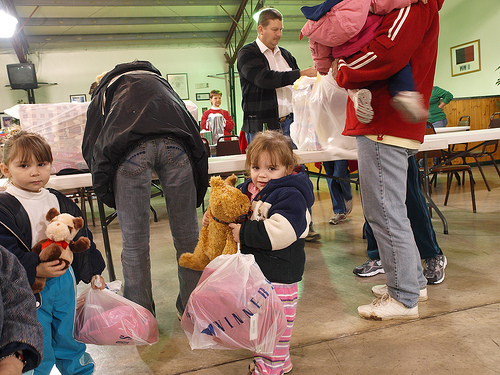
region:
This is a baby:
[2, 127, 109, 373]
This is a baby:
[191, 120, 331, 373]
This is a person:
[80, 50, 212, 354]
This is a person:
[231, 0, 321, 138]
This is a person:
[336, 7, 464, 357]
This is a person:
[197, 81, 238, 147]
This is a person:
[241, 5, 290, 141]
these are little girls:
[28, 69, 381, 341]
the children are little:
[33, 135, 316, 336]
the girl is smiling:
[210, 136, 332, 301]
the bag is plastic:
[209, 243, 296, 347]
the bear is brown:
[183, 177, 266, 264]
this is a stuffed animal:
[192, 169, 279, 284]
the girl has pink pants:
[269, 279, 331, 371]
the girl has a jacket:
[237, 178, 320, 285]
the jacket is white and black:
[241, 181, 350, 318]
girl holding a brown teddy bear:
[193, 181, 252, 258]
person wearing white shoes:
[350, 285, 421, 323]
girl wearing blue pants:
[31, 270, 85, 372]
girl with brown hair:
[3, 130, 51, 172]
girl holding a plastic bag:
[78, 265, 157, 354]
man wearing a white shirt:
[255, 40, 301, 114]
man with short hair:
[250, 0, 285, 35]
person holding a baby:
[306, 0, 451, 115]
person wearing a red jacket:
[362, 0, 441, 140]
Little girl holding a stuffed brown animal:
[177, 130, 315, 373]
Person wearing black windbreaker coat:
[82, 59, 208, 321]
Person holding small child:
[299, 0, 445, 320]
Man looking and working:
[237, 7, 316, 141]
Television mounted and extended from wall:
[5, 61, 57, 107]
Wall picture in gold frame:
[448, 38, 482, 78]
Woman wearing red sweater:
[200, 88, 235, 152]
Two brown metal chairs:
[448, 110, 499, 190]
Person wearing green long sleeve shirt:
[427, 84, 452, 127]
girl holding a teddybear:
[189, 132, 311, 347]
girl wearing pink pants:
[261, 276, 316, 373]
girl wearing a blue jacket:
[230, 181, 317, 289]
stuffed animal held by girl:
[26, 209, 92, 287]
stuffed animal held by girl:
[183, 170, 245, 255]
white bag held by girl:
[191, 247, 291, 359]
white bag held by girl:
[71, 276, 144, 345]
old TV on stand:
[5, 57, 41, 89]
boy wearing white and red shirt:
[203, 82, 234, 140]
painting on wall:
[443, 29, 489, 77]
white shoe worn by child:
[346, 85, 376, 129]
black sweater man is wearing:
[237, 39, 300, 134]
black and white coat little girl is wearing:
[232, 170, 314, 282]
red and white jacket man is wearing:
[341, 0, 443, 145]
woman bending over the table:
[81, 58, 211, 317]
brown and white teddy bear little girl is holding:
[30, 206, 95, 293]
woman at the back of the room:
[198, 89, 235, 140]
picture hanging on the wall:
[447, 39, 482, 76]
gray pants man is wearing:
[357, 134, 428, 303]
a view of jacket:
[78, 56, 190, 178]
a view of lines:
[331, 319, 377, 364]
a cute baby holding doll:
[211, 128, 331, 355]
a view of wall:
[164, 35, 208, 76]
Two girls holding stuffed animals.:
[2, 123, 317, 374]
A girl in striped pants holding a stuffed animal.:
[183, 127, 329, 373]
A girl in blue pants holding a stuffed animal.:
[4, 128, 112, 374]